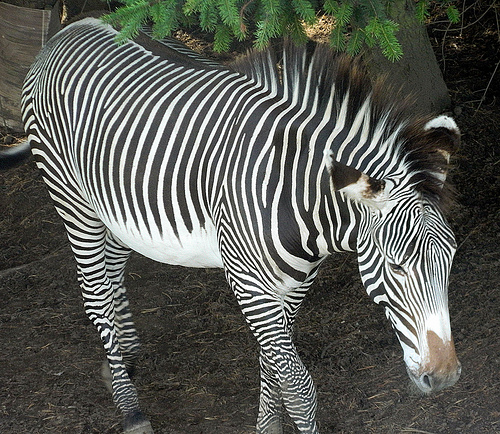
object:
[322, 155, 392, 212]
ear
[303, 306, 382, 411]
dirt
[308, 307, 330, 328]
leaves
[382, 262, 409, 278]
eye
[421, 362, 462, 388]
nose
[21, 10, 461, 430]
zebra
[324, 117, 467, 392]
head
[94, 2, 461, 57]
trees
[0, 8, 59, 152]
post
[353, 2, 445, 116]
tree trunk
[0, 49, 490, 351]
area